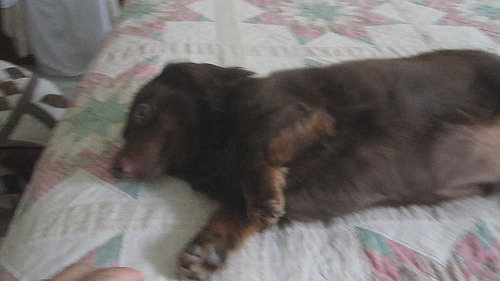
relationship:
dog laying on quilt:
[111, 51, 499, 276] [132, 11, 324, 56]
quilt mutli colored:
[132, 11, 324, 56] [361, 234, 490, 276]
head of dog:
[111, 60, 215, 191] [111, 51, 499, 276]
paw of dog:
[176, 244, 223, 280] [111, 51, 499, 276]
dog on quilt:
[111, 51, 499, 276] [132, 11, 324, 56]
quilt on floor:
[132, 11, 324, 56] [0, 58, 44, 145]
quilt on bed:
[132, 11, 324, 56] [164, 1, 430, 46]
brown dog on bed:
[327, 77, 374, 112] [164, 1, 430, 46]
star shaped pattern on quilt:
[246, 0, 405, 50] [132, 11, 324, 56]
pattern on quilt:
[361, 234, 490, 276] [132, 11, 324, 56]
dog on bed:
[111, 51, 499, 276] [164, 1, 430, 46]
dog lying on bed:
[111, 51, 499, 276] [164, 1, 430, 46]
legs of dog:
[177, 146, 305, 279] [111, 51, 499, 276]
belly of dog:
[344, 132, 496, 193] [111, 51, 499, 276]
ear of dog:
[166, 63, 256, 100] [111, 51, 499, 276]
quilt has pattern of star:
[132, 11, 324, 56] [246, 0, 405, 50]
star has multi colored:
[246, 0, 405, 50] [361, 234, 490, 276]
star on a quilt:
[246, 0, 405, 50] [132, 11, 324, 56]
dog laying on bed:
[111, 51, 499, 276] [164, 1, 430, 46]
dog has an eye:
[111, 51, 499, 276] [134, 101, 150, 121]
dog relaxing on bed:
[111, 51, 499, 276] [164, 1, 430, 46]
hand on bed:
[63, 266, 144, 281] [164, 1, 430, 46]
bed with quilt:
[164, 1, 430, 46] [132, 11, 324, 56]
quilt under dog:
[132, 11, 324, 56] [111, 51, 499, 276]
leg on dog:
[242, 91, 319, 227] [111, 51, 499, 276]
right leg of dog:
[176, 205, 248, 281] [111, 51, 499, 276]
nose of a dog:
[111, 156, 124, 176] [111, 51, 499, 276]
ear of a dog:
[166, 63, 256, 100] [111, 51, 499, 276]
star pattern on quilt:
[246, 0, 405, 50] [132, 11, 324, 56]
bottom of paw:
[186, 248, 217, 274] [176, 244, 223, 280]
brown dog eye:
[327, 77, 374, 112] [134, 101, 150, 121]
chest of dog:
[215, 146, 247, 191] [111, 51, 499, 276]